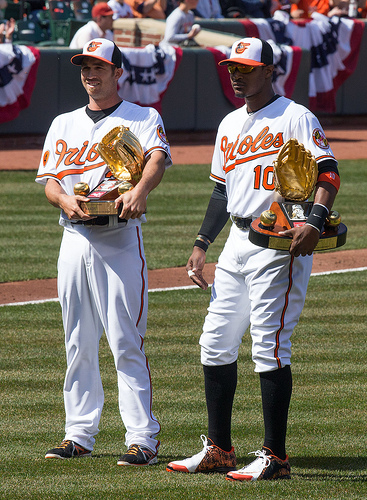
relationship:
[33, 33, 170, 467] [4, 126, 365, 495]
baseball players standing on baseball field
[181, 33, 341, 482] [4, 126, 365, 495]
man standing on baseball field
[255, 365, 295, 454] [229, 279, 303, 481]
sock on leg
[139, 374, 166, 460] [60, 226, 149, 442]
stripe on pants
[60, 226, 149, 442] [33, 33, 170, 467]
pants on baseball players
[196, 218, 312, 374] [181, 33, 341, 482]
pants on man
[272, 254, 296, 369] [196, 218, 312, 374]
stripe on pants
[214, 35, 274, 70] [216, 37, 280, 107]
hat on head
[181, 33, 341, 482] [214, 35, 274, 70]
man wearing hat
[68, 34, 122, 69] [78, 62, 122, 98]
hat on head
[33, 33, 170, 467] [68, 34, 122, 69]
baseball players wearing hat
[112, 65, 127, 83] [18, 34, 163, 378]
left ear on man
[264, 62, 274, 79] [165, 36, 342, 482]
ear on man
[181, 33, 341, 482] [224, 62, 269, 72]
man wearing sunglasses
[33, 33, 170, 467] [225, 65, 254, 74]
baseball players wearing sunglasses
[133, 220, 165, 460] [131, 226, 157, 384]
stripe on pants